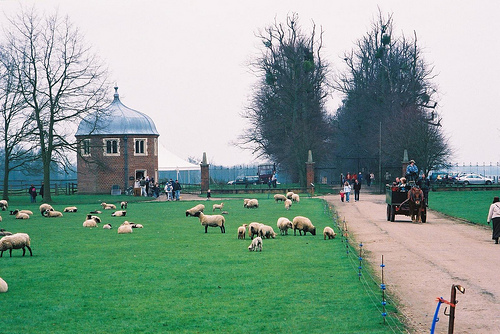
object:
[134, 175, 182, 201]
people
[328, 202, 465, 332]
fence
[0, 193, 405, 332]
field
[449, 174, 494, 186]
car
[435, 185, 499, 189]
road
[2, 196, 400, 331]
grass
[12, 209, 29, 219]
sheep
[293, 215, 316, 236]
sheep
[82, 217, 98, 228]
sheep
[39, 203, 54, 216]
sheep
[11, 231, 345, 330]
green grass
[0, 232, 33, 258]
sheep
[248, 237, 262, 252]
sheep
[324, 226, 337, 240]
sheep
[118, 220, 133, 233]
sheep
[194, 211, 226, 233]
sheep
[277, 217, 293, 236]
sheep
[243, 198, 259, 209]
sheep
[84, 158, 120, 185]
wall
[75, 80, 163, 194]
building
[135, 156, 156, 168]
wall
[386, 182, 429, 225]
wagon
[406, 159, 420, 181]
man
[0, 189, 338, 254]
sheep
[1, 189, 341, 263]
animals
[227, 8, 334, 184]
tree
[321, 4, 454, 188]
tree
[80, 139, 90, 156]
window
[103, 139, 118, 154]
window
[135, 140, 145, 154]
window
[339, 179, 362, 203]
family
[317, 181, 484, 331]
road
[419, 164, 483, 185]
parking lot